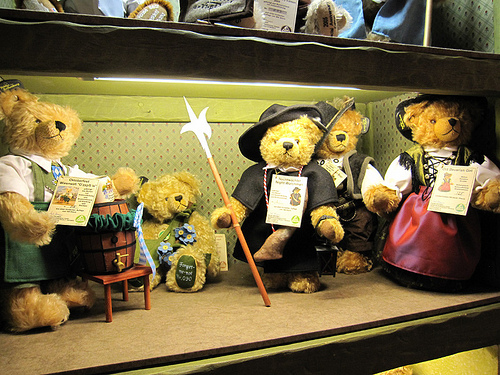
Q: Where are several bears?
A: On a shelf.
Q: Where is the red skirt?
A: On a bear.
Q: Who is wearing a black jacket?
A: The bear.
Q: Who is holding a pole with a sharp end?
A: The bear in black.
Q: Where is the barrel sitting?
A: On a table.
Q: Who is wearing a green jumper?
A: A bear.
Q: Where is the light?
A: Above the bears.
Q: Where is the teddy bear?
A: On the shelf.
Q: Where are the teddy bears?
A: On a shelf.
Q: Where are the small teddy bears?
A: On a store shelf.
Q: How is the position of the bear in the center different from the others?
A: It is sitting down.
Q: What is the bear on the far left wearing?
A: Green pants, suspenders and white shirt.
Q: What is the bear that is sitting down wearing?
A: Green pants.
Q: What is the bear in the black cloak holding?
A: A spear.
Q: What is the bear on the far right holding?
A: A red dress with a green bodice.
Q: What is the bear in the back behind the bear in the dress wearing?
A: Brown pants, a vest and a white shirt.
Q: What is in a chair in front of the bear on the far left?
A: A small keg.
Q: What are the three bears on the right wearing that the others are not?
A: A hat.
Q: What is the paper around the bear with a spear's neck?
A: A certificate of authenticity.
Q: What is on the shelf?
A: Teddy Bears.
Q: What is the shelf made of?
A: Wood.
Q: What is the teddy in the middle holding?
A: Weapon.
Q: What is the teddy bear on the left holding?
A: Paper.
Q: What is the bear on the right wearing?
A: Dress.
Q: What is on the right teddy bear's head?
A: Hat.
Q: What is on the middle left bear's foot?
A: Writing.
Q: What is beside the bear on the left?
A: Keg.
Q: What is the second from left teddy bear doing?
A: Sitting.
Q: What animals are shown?
A: Bears.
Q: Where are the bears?
A: On a shelf.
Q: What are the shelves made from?
A: Wood.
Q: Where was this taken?
A: In a building.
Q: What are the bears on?
A: A shelf.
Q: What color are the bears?
A: Brown.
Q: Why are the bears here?
A: To display to the public.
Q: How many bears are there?
A: Five.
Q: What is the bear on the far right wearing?
A: A dress.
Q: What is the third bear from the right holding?
A: A halberd.